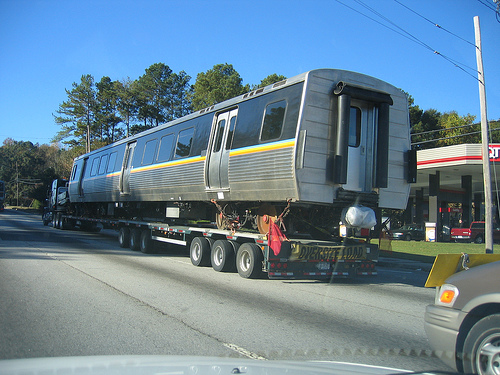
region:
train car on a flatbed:
[48, 70, 426, 236]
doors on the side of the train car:
[74, 112, 241, 193]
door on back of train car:
[340, 90, 372, 192]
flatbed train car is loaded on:
[62, 205, 362, 292]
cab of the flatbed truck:
[40, 178, 65, 225]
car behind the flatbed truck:
[419, 264, 499, 364]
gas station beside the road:
[411, 127, 493, 249]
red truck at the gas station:
[450, 218, 491, 246]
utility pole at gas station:
[466, 11, 498, 258]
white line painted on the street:
[222, 337, 272, 364]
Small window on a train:
[252, 93, 294, 149]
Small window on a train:
[347, 102, 363, 157]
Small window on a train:
[215, 113, 224, 158]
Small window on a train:
[221, 113, 239, 169]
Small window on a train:
[172, 121, 192, 167]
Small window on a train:
[156, 131, 176, 174]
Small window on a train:
[134, 132, 161, 172]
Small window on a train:
[103, 149, 120, 176]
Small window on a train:
[99, 150, 110, 181]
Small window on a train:
[86, 157, 101, 181]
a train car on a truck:
[38, 47, 439, 262]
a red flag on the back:
[260, 203, 301, 268]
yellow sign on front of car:
[413, 230, 495, 287]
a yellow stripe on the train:
[53, 147, 310, 195]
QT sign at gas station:
[476, 138, 499, 168]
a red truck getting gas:
[427, 210, 497, 257]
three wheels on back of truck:
[176, 229, 267, 280]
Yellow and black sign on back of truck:
[287, 233, 382, 276]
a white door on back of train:
[336, 95, 381, 200]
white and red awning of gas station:
[417, 127, 499, 204]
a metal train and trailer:
[19, 43, 434, 341]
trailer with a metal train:
[9, 65, 497, 365]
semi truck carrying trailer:
[14, 91, 404, 343]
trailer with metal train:
[37, 77, 499, 351]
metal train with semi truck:
[23, 78, 428, 370]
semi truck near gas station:
[44, 44, 496, 374]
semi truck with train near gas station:
[19, 57, 476, 374]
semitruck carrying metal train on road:
[27, 46, 448, 372]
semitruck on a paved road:
[36, 116, 421, 364]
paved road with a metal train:
[39, 61, 454, 373]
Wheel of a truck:
[234, 238, 268, 290]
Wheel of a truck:
[204, 231, 236, 276]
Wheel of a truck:
[183, 231, 214, 273]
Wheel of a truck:
[138, 225, 158, 252]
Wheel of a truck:
[126, 225, 142, 254]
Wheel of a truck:
[112, 225, 127, 245]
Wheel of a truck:
[59, 215, 66, 230]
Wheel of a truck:
[52, 218, 60, 229]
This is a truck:
[39, 58, 429, 280]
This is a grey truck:
[14, 63, 445, 318]